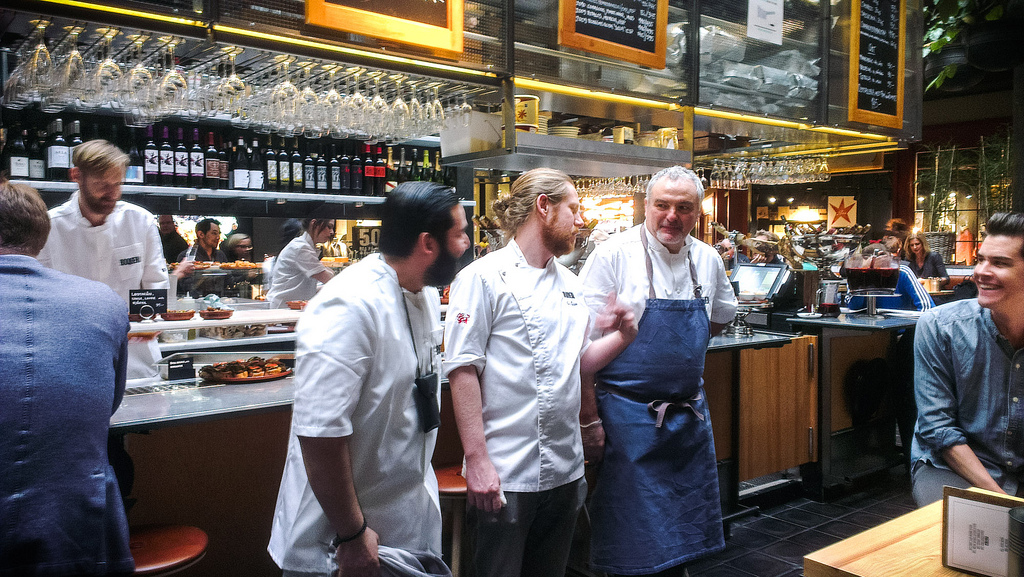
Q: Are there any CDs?
A: No, there are no cds.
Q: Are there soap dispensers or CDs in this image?
A: No, there are no CDs or soap dispensers.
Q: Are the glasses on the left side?
A: Yes, the glasses are on the left of the image.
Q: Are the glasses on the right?
A: No, the glasses are on the left of the image.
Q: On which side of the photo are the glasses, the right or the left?
A: The glasses are on the left of the image.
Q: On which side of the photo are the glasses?
A: The glasses are on the left of the image.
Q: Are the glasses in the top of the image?
A: Yes, the glasses are in the top of the image.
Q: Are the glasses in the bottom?
A: No, the glasses are in the top of the image.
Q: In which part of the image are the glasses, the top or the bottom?
A: The glasses are in the top of the image.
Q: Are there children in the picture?
A: No, there are no children.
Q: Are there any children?
A: No, there are no children.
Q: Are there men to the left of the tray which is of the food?
A: Yes, there is a man to the left of the tray.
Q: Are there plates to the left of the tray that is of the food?
A: No, there is a man to the left of the tray.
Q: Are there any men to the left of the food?
A: Yes, there is a man to the left of the food.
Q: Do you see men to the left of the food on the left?
A: Yes, there is a man to the left of the food.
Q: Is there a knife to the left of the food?
A: No, there is a man to the left of the food.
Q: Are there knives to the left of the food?
A: No, there is a man to the left of the food.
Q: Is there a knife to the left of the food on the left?
A: No, there is a man to the left of the food.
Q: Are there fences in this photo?
A: No, there are no fences.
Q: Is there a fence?
A: No, there are no fences.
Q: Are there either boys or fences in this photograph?
A: No, there are no fences or boys.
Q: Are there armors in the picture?
A: No, there are no armors.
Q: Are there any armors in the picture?
A: No, there are no armors.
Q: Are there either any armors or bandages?
A: No, there are no armors or bandages.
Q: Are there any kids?
A: No, there are no kids.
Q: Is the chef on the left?
A: Yes, the chef is on the left of the image.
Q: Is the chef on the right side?
A: No, the chef is on the left of the image.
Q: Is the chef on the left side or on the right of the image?
A: The chef is on the left of the image.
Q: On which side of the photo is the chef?
A: The chef is on the left of the image.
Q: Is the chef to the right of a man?
A: No, the chef is to the left of a man.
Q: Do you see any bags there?
A: No, there are no bags.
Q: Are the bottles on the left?
A: Yes, the bottles are on the left of the image.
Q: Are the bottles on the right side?
A: No, the bottles are on the left of the image.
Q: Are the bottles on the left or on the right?
A: The bottles are on the left of the image.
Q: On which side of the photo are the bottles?
A: The bottles are on the left of the image.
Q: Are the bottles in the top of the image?
A: Yes, the bottles are in the top of the image.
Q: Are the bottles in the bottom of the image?
A: No, the bottles are in the top of the image.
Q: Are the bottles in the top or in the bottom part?
A: The bottles are in the top of the image.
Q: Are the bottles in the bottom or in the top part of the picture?
A: The bottles are in the top of the image.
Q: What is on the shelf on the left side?
A: The bottles are on the shelf.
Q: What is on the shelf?
A: The bottles are on the shelf.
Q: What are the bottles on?
A: The bottles are on the shelf.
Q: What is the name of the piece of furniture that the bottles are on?
A: The piece of furniture is a shelf.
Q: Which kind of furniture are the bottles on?
A: The bottles are on the shelf.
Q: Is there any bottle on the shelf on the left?
A: Yes, there are bottles on the shelf.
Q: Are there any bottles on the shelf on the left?
A: Yes, there are bottles on the shelf.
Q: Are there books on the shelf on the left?
A: No, there are bottles on the shelf.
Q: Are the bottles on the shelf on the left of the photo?
A: Yes, the bottles are on the shelf.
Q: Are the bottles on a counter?
A: No, the bottles are on the shelf.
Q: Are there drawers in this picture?
A: No, there are no drawers.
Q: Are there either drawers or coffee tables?
A: No, there are no drawers or coffee tables.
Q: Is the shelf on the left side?
A: Yes, the shelf is on the left of the image.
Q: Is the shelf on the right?
A: No, the shelf is on the left of the image.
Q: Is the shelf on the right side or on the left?
A: The shelf is on the left of the image.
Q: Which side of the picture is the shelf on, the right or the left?
A: The shelf is on the left of the image.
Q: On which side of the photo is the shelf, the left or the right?
A: The shelf is on the left of the image.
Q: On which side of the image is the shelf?
A: The shelf is on the left of the image.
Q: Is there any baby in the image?
A: No, there are no babies.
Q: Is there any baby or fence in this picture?
A: No, there are no babies or fences.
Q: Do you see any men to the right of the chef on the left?
A: Yes, there is a man to the right of the chef.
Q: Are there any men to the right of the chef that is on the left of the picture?
A: Yes, there is a man to the right of the chef.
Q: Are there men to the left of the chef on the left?
A: No, the man is to the right of the chef.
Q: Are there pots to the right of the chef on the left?
A: No, there is a man to the right of the chef.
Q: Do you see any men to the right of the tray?
A: Yes, there is a man to the right of the tray.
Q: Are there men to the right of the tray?
A: Yes, there is a man to the right of the tray.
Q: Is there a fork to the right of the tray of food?
A: No, there is a man to the right of the tray.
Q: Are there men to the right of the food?
A: Yes, there is a man to the right of the food.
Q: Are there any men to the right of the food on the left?
A: Yes, there is a man to the right of the food.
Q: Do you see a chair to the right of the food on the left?
A: No, there is a man to the right of the food.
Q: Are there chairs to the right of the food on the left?
A: No, there is a man to the right of the food.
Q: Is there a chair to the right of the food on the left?
A: No, there is a man to the right of the food.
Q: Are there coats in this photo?
A: Yes, there is a coat.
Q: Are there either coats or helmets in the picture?
A: Yes, there is a coat.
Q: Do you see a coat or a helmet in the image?
A: Yes, there is a coat.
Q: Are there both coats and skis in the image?
A: No, there is a coat but no skis.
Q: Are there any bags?
A: No, there are no bags.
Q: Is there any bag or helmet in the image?
A: No, there are no bags or helmets.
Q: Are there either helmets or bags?
A: No, there are no bags or helmets.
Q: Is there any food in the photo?
A: Yes, there is food.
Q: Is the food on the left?
A: Yes, the food is on the left of the image.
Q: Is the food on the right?
A: No, the food is on the left of the image.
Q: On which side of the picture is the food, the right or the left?
A: The food is on the left of the image.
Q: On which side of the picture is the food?
A: The food is on the left of the image.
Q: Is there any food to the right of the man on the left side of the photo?
A: Yes, there is food to the right of the man.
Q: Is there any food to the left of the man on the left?
A: No, the food is to the right of the man.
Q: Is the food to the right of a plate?
A: No, the food is to the right of a man.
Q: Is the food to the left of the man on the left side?
A: No, the food is to the right of the man.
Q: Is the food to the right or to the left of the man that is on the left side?
A: The food is to the right of the man.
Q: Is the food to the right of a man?
A: No, the food is to the left of a man.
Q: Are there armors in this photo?
A: No, there are no armors.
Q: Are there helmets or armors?
A: No, there are no armors or helmets.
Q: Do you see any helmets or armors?
A: No, there are no armors or helmets.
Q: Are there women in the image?
A: Yes, there is a woman.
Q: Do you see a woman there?
A: Yes, there is a woman.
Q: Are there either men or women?
A: Yes, there is a woman.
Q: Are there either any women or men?
A: Yes, there is a woman.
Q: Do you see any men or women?
A: Yes, there is a woman.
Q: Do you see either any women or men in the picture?
A: Yes, there is a woman.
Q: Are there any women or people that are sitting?
A: Yes, the woman is sitting.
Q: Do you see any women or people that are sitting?
A: Yes, the woman is sitting.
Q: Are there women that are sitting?
A: Yes, there is a woman that is sitting.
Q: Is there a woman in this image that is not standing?
A: Yes, there is a woman that is sitting.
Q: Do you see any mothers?
A: No, there are no mothers.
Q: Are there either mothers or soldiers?
A: No, there are no mothers or soldiers.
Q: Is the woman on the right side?
A: Yes, the woman is on the right of the image.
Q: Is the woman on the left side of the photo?
A: No, the woman is on the right of the image.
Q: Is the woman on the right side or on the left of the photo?
A: The woman is on the right of the image.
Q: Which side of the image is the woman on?
A: The woman is on the right of the image.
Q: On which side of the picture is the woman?
A: The woman is on the right of the image.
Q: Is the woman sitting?
A: Yes, the woman is sitting.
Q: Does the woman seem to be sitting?
A: Yes, the woman is sitting.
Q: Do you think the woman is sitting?
A: Yes, the woman is sitting.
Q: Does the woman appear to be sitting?
A: Yes, the woman is sitting.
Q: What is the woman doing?
A: The woman is sitting.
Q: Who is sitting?
A: The woman is sitting.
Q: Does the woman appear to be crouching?
A: No, the woman is sitting.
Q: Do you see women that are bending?
A: No, there is a woman but she is sitting.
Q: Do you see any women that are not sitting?
A: No, there is a woman but she is sitting.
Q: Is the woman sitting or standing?
A: The woman is sitting.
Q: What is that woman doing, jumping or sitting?
A: The woman is sitting.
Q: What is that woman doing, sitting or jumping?
A: The woman is sitting.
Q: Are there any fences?
A: No, there are no fences.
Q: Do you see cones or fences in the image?
A: No, there are no fences or cones.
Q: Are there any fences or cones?
A: No, there are no fences or cones.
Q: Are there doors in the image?
A: Yes, there is a door.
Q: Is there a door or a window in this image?
A: Yes, there is a door.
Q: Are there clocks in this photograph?
A: No, there are no clocks.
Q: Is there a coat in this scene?
A: Yes, there is a coat.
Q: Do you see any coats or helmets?
A: Yes, there is a coat.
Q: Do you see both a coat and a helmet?
A: No, there is a coat but no helmets.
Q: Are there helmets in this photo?
A: No, there are no helmets.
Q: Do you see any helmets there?
A: No, there are no helmets.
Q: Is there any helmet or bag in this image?
A: No, there are no helmets or bags.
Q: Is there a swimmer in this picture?
A: No, there are no swimmers.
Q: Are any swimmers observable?
A: No, there are no swimmers.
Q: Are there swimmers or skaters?
A: No, there are no swimmers or skaters.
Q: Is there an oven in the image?
A: No, there are no ovens.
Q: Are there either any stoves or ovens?
A: No, there are no ovens or stoves.